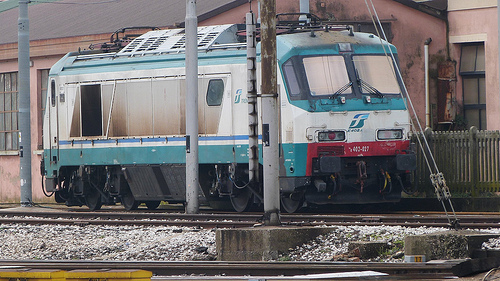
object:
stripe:
[44, 61, 410, 141]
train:
[38, 15, 419, 216]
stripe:
[306, 139, 407, 181]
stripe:
[54, 49, 250, 72]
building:
[2, 1, 498, 210]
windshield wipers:
[282, 54, 404, 98]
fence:
[411, 129, 500, 198]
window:
[77, 82, 107, 136]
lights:
[317, 131, 346, 142]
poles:
[182, 1, 199, 219]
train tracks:
[0, 218, 500, 230]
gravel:
[3, 221, 448, 262]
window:
[1, 70, 18, 154]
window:
[35, 67, 49, 157]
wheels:
[80, 167, 106, 209]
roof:
[0, 1, 240, 46]